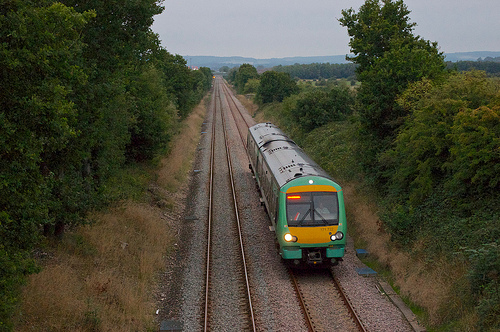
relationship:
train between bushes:
[244, 120, 354, 273] [1, 2, 496, 329]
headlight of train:
[282, 233, 298, 245] [244, 120, 354, 273]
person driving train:
[315, 201, 330, 216] [244, 120, 354, 273]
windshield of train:
[287, 192, 339, 225] [244, 120, 354, 273]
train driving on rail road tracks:
[244, 120, 354, 273] [170, 68, 414, 330]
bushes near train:
[1, 2, 496, 329] [244, 120, 354, 273]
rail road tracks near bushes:
[170, 68, 414, 330] [1, 2, 496, 329]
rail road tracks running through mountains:
[170, 68, 414, 330] [174, 52, 496, 72]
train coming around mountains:
[244, 120, 354, 273] [174, 52, 496, 72]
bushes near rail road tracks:
[1, 2, 496, 329] [170, 68, 414, 330]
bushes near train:
[1, 2, 496, 329] [244, 122, 349, 272]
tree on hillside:
[341, 2, 481, 122] [282, 58, 482, 194]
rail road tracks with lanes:
[170, 68, 414, 330] [204, 76, 346, 330]